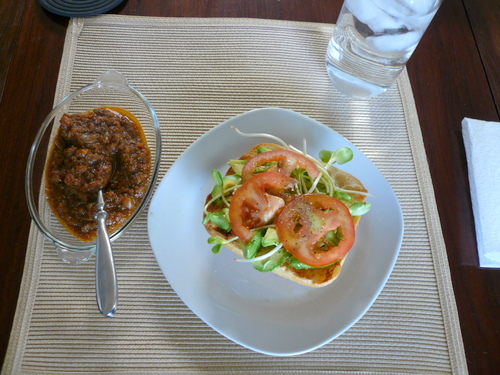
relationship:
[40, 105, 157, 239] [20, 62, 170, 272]
food in bowl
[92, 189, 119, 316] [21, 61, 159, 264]
spoon in bowl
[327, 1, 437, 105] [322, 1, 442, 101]
water in glass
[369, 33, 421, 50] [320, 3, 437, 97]
ice in glass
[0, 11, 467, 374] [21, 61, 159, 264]
tablecloth under bowl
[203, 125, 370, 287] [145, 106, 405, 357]
food in plate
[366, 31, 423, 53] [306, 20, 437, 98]
ice in glass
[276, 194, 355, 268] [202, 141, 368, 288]
tomatoe on top of bread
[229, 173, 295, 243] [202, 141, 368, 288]
tomato on top of bread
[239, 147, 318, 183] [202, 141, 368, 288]
tomato on top of bread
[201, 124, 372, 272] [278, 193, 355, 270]
greens under tomatoes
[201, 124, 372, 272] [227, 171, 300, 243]
greens under tomato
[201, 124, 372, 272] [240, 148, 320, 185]
greens under tomato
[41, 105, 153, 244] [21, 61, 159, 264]
food inside bowl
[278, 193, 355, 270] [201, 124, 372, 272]
tomatoes on top of greens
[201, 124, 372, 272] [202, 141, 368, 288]
greens on top of bread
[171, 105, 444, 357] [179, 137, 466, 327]
bowl with food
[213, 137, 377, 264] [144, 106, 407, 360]
vegetable on bowl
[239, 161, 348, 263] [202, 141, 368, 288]
tomatoes on bread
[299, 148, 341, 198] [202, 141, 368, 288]
sprouts on bread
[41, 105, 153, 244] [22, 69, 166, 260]
food in bowl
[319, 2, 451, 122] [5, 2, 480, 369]
glass on table